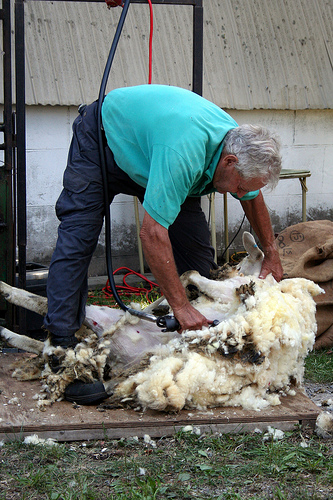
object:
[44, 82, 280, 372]
man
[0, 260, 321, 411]
sheep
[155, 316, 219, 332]
clippers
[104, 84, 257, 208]
shirt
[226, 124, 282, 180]
hair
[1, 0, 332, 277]
building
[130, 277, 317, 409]
wool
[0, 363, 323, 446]
wood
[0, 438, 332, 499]
grass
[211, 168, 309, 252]
table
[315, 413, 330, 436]
wool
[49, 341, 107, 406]
boot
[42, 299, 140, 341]
legs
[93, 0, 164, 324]
chord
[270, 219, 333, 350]
bag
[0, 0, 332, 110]
roof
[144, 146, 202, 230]
sleeve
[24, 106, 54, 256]
wall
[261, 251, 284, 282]
hand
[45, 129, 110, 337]
pants